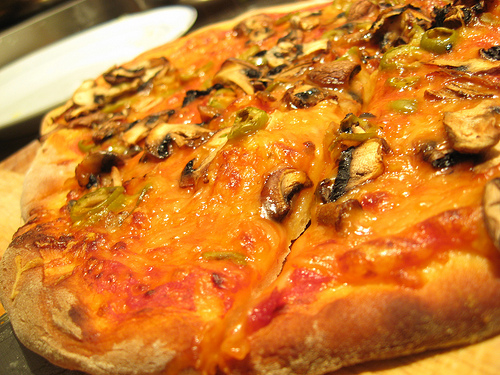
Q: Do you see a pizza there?
A: Yes, there is a pizza.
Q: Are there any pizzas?
A: Yes, there is a pizza.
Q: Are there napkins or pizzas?
A: Yes, there is a pizza.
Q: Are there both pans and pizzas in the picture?
A: No, there is a pizza but no pans.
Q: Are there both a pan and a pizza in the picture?
A: No, there is a pizza but no pans.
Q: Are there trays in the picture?
A: No, there are no trays.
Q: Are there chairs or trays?
A: No, there are no trays or chairs.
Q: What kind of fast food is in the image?
A: The fast food is a pizza.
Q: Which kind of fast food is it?
A: The food is a pizza.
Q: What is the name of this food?
A: This is a pizza.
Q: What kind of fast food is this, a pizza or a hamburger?
A: This is a pizza.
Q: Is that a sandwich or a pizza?
A: That is a pizza.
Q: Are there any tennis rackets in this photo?
A: No, there are no tennis rackets.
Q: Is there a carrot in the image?
A: No, there are no carrots.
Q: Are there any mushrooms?
A: Yes, there are mushrooms.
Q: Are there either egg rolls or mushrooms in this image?
A: Yes, there are mushrooms.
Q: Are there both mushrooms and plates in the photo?
A: Yes, there are both mushrooms and a plate.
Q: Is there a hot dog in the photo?
A: No, there are no hot dogs.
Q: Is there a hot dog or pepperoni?
A: No, there are no hot dogs or pepperoni.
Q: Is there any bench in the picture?
A: No, there are no benches.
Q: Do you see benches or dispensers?
A: No, there are no benches or dispensers.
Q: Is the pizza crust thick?
A: Yes, the pizza crust is thick.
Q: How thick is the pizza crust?
A: The pizza crust is thick.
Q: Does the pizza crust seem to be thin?
A: No, the pizza crust is thick.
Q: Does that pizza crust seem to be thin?
A: No, the pizza crust is thick.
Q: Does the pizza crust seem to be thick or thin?
A: The pizza crust is thick.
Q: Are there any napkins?
A: No, there are no napkins.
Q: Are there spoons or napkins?
A: No, there are no napkins or spoons.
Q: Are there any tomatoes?
A: No, there are no tomatoes.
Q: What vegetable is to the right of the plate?
A: The vegetable is an olive.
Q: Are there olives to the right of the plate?
A: Yes, there is an olive to the right of the plate.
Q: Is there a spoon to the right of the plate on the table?
A: No, there is an olive to the right of the plate.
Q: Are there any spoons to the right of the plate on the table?
A: No, there is an olive to the right of the plate.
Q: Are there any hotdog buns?
A: No, there are no hotdog buns.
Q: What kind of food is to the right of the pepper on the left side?
A: The food is a mushroom.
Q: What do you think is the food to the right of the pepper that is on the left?
A: The food is a mushroom.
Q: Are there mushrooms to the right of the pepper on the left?
A: Yes, there is a mushroom to the right of the pepper.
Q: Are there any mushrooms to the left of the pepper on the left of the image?
A: No, the mushroom is to the right of the pepper.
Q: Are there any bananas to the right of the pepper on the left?
A: No, there is a mushroom to the right of the pepper.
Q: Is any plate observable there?
A: Yes, there is a plate.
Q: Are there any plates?
A: Yes, there is a plate.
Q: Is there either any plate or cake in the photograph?
A: Yes, there is a plate.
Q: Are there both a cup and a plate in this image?
A: No, there is a plate but no cups.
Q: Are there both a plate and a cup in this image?
A: No, there is a plate but no cups.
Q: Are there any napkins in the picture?
A: No, there are no napkins.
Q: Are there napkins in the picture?
A: No, there are no napkins.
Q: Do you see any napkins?
A: No, there are no napkins.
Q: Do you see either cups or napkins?
A: No, there are no napkins or cups.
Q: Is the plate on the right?
A: No, the plate is on the left of the image.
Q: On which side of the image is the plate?
A: The plate is on the left of the image.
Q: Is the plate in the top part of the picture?
A: Yes, the plate is in the top of the image.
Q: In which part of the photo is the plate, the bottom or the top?
A: The plate is in the top of the image.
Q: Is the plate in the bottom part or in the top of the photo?
A: The plate is in the top of the image.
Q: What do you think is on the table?
A: The plate is on the table.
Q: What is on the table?
A: The plate is on the table.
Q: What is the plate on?
A: The plate is on the table.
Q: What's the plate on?
A: The plate is on the table.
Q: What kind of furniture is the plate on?
A: The plate is on the table.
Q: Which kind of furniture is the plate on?
A: The plate is on the table.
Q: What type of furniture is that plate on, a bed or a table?
A: The plate is on a table.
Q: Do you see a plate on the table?
A: Yes, there is a plate on the table.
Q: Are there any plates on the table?
A: Yes, there is a plate on the table.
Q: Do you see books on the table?
A: No, there is a plate on the table.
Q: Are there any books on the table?
A: No, there is a plate on the table.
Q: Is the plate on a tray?
A: No, the plate is on the table.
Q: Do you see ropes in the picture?
A: No, there are no ropes.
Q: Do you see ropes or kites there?
A: No, there are no ropes or kites.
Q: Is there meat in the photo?
A: No, there is no meat.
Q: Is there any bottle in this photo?
A: No, there are no bottles.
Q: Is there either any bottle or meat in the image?
A: No, there are no bottles or meat.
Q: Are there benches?
A: No, there are no benches.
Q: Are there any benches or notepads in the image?
A: No, there are no benches or notepads.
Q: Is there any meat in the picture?
A: No, there is no meat.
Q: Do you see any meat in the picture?
A: No, there is no meat.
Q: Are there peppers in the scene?
A: Yes, there is a pepper.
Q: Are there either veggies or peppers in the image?
A: Yes, there is a pepper.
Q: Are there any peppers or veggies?
A: Yes, there is a pepper.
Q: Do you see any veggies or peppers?
A: Yes, there is a pepper.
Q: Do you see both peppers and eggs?
A: No, there is a pepper but no eggs.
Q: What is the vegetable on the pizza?
A: The vegetable is a pepper.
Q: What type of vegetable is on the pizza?
A: The vegetable is a pepper.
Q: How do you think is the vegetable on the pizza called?
A: The vegetable is a pepper.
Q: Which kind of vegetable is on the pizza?
A: The vegetable is a pepper.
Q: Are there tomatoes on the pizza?
A: No, there is a pepper on the pizza.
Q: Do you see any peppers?
A: Yes, there is a pepper.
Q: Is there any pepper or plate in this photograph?
A: Yes, there is a pepper.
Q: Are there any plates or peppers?
A: Yes, there is a pepper.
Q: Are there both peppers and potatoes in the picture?
A: No, there is a pepper but no potatoes.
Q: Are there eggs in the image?
A: No, there are no eggs.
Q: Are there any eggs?
A: No, there are no eggs.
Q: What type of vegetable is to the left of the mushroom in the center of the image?
A: The vegetable is a pepper.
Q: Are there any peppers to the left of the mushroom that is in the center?
A: Yes, there is a pepper to the left of the mushroom.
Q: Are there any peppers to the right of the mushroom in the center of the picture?
A: No, the pepper is to the left of the mushroom.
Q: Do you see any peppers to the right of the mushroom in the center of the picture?
A: No, the pepper is to the left of the mushroom.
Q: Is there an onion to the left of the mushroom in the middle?
A: No, there is a pepper to the left of the mushroom.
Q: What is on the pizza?
A: The pepper is on the pizza.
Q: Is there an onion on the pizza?
A: No, there is a pepper on the pizza.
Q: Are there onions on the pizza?
A: No, there is a pepper on the pizza.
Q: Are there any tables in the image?
A: Yes, there is a table.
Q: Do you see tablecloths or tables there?
A: Yes, there is a table.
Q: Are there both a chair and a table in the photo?
A: No, there is a table but no chairs.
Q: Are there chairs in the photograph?
A: No, there are no chairs.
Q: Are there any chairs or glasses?
A: No, there are no chairs or glasses.